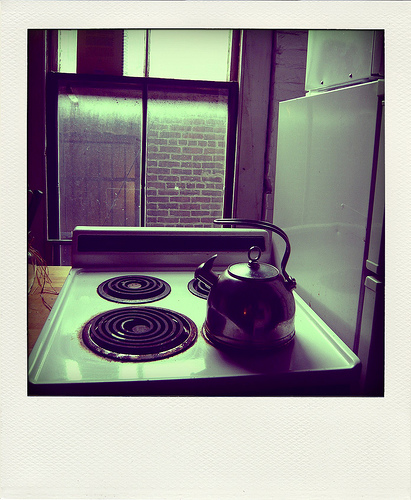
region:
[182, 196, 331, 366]
this is a kettle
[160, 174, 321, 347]
the kettle is on the stove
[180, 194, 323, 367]
the kettle is on an electric burner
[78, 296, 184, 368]
this is the burner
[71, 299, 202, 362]
the burner is a coil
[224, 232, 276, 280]
this is the lid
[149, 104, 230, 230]
the brick wall of another building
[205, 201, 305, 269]
this is the handle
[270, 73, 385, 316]
this is the refrigerator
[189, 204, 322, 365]
This is a kettle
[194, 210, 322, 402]
This is a kettle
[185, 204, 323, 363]
This is a kettle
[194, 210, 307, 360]
This is a kettle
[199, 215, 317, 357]
This is a kettle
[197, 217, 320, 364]
This is a kettle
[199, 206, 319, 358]
This is a kettle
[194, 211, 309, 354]
This is a kettle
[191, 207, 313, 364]
This is a kettle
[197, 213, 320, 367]
This is a kettle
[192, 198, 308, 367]
a metal kettle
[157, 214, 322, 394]
a metal kettle on the stove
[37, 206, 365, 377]
a metal stove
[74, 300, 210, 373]
a black stove coil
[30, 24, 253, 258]
a closed window in a wall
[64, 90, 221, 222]
a wall of bricks outside a window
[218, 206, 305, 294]
the handle of a kettle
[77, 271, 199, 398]
two different sized coils on a stove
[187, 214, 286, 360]
black tea pot on stove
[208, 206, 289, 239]
black handle to tea pot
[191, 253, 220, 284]
black spout to tea pot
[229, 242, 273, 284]
black lid to tea pot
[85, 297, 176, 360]
black bottom of stove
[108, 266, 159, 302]
black electric stove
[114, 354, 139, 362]
rust around side of stove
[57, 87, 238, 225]
small window behind stove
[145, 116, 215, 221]
brick wall outside of window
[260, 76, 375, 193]
white side of fridge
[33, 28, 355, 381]
a stove top sits in front of a window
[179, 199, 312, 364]
a tea kettle sits on the stove top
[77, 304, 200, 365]
one of the bigger burners on the stove top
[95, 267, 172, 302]
one of the smaller burners on the stove top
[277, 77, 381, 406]
the fridge is next to the stove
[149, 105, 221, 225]
a brick building can be seen through the window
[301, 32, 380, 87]
an appliance sits on the fridge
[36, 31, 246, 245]
a window is behind the stove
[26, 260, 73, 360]
a portion of the counter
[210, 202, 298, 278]
the tea kettles handle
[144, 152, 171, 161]
red brick in the wall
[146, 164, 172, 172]
red brick in the wall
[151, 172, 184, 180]
red brick in the wall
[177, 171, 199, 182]
red brick in the wall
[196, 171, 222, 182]
red brick in the wall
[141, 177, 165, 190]
red brick in the wall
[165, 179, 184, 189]
red brick in the wall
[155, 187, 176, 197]
red brick in the wall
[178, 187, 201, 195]
red brick in the wall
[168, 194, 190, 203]
red brick in the wall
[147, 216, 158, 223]
red brick on wall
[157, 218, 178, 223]
red brick on wall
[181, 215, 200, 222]
red brick on wall